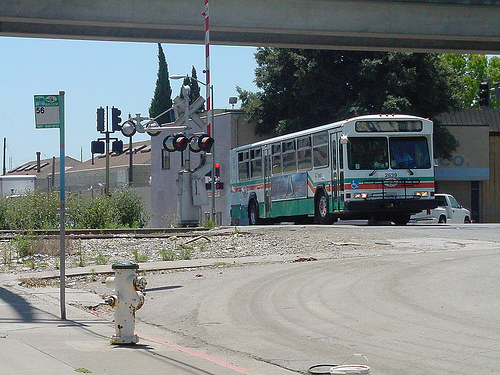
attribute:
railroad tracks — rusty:
[69, 211, 189, 250]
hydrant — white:
[101, 258, 151, 350]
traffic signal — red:
[211, 159, 222, 180]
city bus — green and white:
[222, 114, 438, 220]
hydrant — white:
[83, 226, 163, 342]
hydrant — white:
[100, 253, 154, 370]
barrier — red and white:
[203, 1, 211, 135]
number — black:
[386, 174, 398, 181]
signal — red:
[203, 152, 230, 177]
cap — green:
[110, 257, 139, 272]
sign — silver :
[259, 171, 315, 201]